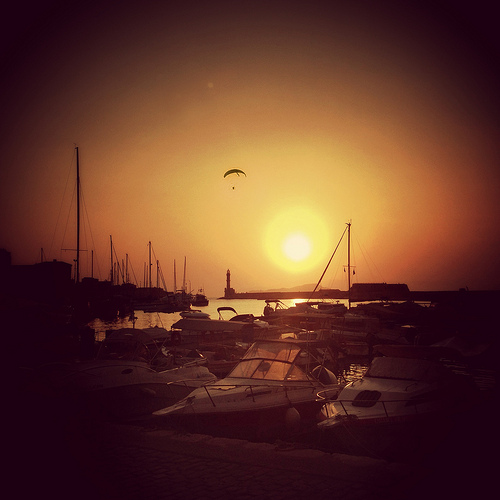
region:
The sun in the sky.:
[264, 223, 321, 268]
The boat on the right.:
[323, 345, 483, 451]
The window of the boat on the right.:
[367, 355, 437, 378]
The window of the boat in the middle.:
[236, 341, 313, 384]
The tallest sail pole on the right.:
[62, 139, 98, 291]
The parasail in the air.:
[216, 165, 248, 192]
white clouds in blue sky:
[137, 71, 172, 122]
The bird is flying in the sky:
[212, 155, 260, 201]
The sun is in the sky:
[262, 208, 352, 284]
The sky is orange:
[96, 115, 428, 302]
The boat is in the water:
[162, 289, 221, 322]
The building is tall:
[215, 260, 241, 299]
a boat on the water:
[187, 345, 342, 423]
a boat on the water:
[323, 357, 435, 460]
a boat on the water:
[128, 342, 209, 397]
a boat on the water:
[180, 305, 215, 320]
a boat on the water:
[107, 321, 171, 336]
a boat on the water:
[190, 285, 208, 306]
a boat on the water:
[276, 222, 388, 335]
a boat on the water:
[137, 245, 174, 315]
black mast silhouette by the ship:
[73, 140, 82, 284]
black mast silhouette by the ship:
[86, 246, 94, 278]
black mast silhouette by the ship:
[105, 230, 115, 285]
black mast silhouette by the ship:
[180, 252, 186, 293]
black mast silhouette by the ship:
[121, 247, 128, 287]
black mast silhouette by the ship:
[114, 255, 119, 285]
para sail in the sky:
[218, 160, 252, 187]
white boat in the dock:
[326, 330, 463, 460]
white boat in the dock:
[158, 318, 324, 432]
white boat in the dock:
[61, 337, 212, 407]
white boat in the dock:
[159, 303, 269, 345]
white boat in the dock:
[319, 297, 394, 353]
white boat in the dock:
[326, 322, 441, 432]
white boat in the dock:
[168, 303, 255, 342]